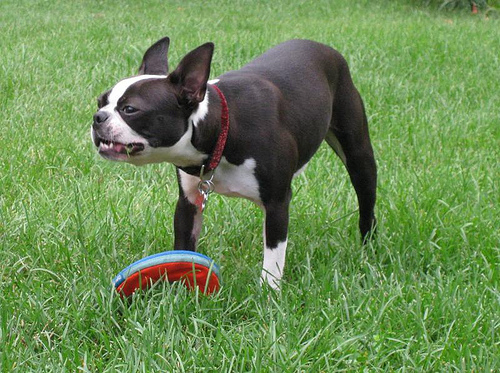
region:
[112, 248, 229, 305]
a red and blue freebie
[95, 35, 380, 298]
a black and white dog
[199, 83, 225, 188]
a red collar on a dog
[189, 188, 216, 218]
a tag on a coller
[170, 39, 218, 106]
a ear of a dog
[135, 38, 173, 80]
right ear of a dog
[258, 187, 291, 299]
a left leg of a dog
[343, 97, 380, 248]
left rear leg of a dog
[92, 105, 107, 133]
a nose on a dog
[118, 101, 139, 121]
a eye on a dog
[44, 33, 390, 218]
dog in the grass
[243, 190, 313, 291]
black and white leg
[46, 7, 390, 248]
black and white dog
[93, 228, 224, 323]
object on the ground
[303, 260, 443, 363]
many blades of grass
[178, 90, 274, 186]
collar around dog's neck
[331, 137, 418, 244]
back leg of the dog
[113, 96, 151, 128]
eye of the dog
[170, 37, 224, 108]
ear of the dog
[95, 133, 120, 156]
teeth of the dog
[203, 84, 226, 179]
the dog red collar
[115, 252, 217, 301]
black and red dog toy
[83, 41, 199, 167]
the head of the dog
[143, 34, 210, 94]
the two ears of the dog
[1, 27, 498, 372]
a dog playing in the field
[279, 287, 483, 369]
tall grass in the field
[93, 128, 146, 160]
the open mouth of the dog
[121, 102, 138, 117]
one open eye of the dog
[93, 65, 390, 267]
a white and dark brown dog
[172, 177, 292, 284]
the two front legs of the dog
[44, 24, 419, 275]
a dog standing on the grass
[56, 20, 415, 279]
the dog is black and white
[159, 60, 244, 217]
the collar is red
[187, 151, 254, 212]
the chest is white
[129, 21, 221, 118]
the ears are pointy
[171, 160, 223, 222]
the collar has tags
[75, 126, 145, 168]
the mouth is slightly open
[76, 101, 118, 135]
the nose is black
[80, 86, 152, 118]
the eyes are open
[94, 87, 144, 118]
the eyes are dark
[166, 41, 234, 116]
Dog has black ear.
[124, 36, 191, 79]
Dog has black ear.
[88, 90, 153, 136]
Dog has dark eyes.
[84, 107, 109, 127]
Dog has black nose.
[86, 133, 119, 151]
Dog has white teeth.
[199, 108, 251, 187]
Dog wearing red collar.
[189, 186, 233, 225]
Tags hanging from collar.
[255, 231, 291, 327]
Front paw is white.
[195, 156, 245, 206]
Dog has white chest.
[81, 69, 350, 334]
Dog is standing in grassy area.